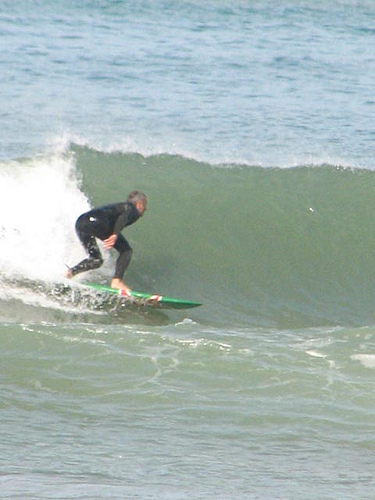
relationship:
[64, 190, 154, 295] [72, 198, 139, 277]
surfer wearing wetsuit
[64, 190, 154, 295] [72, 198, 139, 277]
surfer in wetsuit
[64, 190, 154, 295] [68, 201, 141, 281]
surfer in clothing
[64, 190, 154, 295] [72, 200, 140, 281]
surfer wearing clothing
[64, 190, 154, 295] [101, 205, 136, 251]
surfer's arm lowered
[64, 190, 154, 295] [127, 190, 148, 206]
surfer has grey hair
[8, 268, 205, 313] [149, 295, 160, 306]
surfboard marked red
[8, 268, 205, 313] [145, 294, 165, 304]
surfboard marked white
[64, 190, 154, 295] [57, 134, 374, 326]
surfer riding wave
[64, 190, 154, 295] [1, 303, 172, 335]
surfer casting shadow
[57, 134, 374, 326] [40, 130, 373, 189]
wave rising high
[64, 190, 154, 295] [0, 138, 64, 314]
surfer splashing water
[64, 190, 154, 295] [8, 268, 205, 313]
man on surfboard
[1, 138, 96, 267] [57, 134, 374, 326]
foam in wave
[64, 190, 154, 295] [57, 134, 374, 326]
surfer riding waves